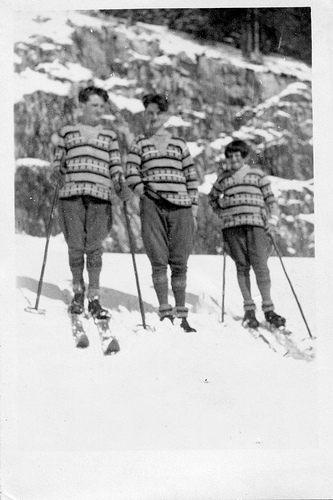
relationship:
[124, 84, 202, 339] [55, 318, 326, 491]
man on snow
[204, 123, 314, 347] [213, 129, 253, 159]
woman has hair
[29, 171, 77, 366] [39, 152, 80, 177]
pole in hand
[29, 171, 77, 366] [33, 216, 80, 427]
pole on right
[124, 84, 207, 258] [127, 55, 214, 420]
man in middle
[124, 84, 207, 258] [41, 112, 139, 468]
man on left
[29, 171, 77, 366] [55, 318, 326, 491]
pole in snow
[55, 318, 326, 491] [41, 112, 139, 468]
snow on left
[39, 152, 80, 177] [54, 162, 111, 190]
hand in pocket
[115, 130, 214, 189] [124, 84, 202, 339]
sweater on man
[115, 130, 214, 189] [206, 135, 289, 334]
sweater on woman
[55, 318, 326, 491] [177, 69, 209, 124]
snow on stone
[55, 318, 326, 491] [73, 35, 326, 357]
snow in area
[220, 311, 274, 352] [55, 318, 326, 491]
ski in snow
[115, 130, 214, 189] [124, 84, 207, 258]
sweater on man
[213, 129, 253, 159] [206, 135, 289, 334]
hair on woman